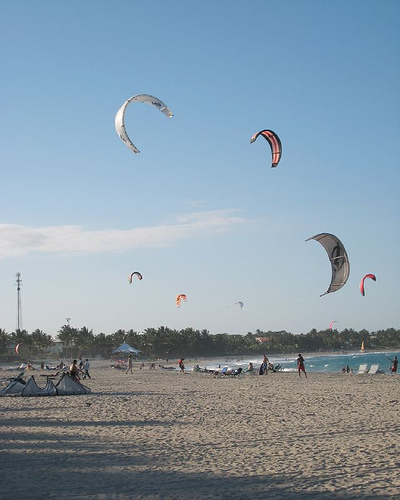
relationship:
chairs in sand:
[356, 361, 379, 375] [0, 351, 397, 499]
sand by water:
[0, 351, 397, 499] [208, 350, 398, 372]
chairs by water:
[356, 361, 379, 375] [208, 350, 398, 372]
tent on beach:
[110, 340, 142, 360] [0, 347, 399, 497]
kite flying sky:
[174, 290, 186, 304] [0, 0, 398, 333]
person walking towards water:
[124, 354, 134, 377] [218, 349, 398, 371]